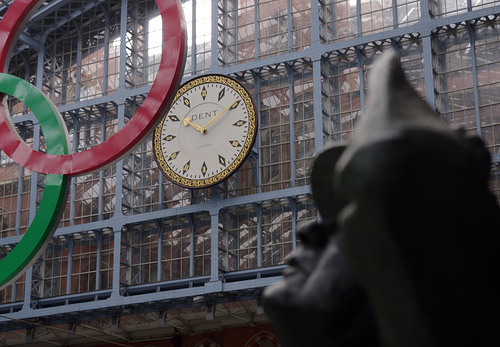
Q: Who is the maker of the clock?
A: Dent.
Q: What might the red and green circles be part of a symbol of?
A: The olympics.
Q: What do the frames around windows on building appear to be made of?
A: Metal.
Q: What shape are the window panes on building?
A: Rectangular.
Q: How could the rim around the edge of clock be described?
A: Gold toned.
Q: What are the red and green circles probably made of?
A: Metal.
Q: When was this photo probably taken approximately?
A: 10:10 a.m.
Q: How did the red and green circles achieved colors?
A: From paint.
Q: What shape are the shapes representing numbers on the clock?
A: Diamond.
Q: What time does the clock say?
A: 10:10.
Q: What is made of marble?
A: A statue.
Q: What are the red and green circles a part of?
A: Olympic symbol.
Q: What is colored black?
A: The statue.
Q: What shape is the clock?
A: Round.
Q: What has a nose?
A: Black statue.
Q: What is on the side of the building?
A: The clock.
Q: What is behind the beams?
A: The window.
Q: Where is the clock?
A: On the wall.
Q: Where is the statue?
A: On the foreground.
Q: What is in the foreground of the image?
A: The statue.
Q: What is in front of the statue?
A: Two circles.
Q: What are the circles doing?
A: Connecting to each other.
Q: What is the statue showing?
A: The face.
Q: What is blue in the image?
A: The bars on the building.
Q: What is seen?
A: Clock.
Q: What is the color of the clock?
A: Golden and white.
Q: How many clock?
A: 1.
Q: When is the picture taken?
A: Daytime.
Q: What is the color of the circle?
A: Red and green.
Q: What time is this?
A: 10:10.